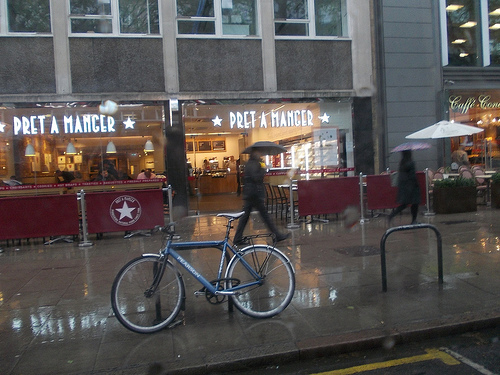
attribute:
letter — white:
[230, 112, 236, 129]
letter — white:
[237, 112, 244, 128]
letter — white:
[244, 112, 249, 128]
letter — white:
[260, 110, 267, 128]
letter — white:
[271, 112, 279, 127]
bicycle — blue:
[112, 211, 295, 333]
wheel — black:
[227, 246, 295, 318]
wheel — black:
[111, 255, 184, 334]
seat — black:
[216, 211, 245, 220]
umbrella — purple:
[389, 141, 432, 153]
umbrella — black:
[241, 141, 288, 155]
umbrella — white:
[404, 120, 484, 139]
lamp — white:
[106, 142, 116, 153]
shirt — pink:
[137, 172, 158, 179]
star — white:
[212, 115, 223, 127]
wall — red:
[297, 176, 361, 215]